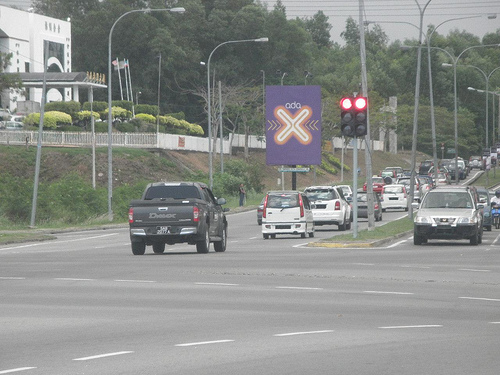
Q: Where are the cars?
A: On the street.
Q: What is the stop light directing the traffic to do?
A: Stop.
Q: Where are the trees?
A: Behind the road.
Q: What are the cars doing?
A: Waiting in traffic.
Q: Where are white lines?
A: On the street.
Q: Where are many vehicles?
A: On the road.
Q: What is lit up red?
A: Traffic lights.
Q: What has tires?
A: The vehicles.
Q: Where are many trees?
A: In the distance.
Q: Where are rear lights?
A: On backs of vehicles.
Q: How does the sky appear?
A: Overcast.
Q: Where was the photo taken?
A: Near a busy street.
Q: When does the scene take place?
A: During the daytime.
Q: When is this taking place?
A: Daytime.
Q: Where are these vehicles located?
A: Street.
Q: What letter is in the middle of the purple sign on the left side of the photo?
A: X.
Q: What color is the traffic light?
A: Red.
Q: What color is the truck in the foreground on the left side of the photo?
A: Black.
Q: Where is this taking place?
A: At an intersection.